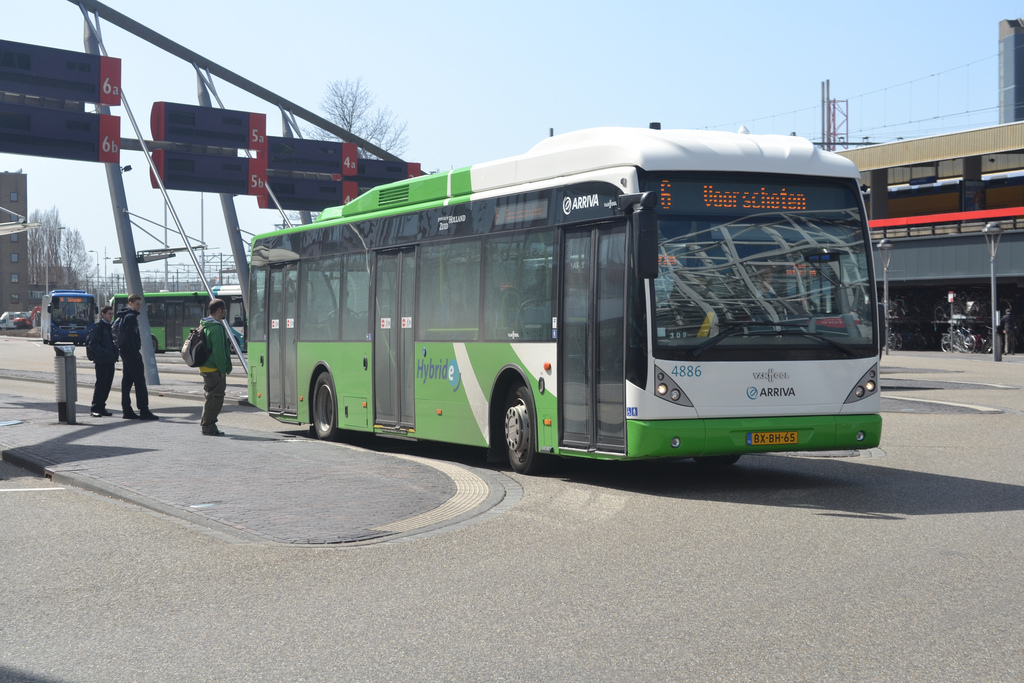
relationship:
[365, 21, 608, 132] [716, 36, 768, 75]
clouds in sky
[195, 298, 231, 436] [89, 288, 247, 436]
man standing in group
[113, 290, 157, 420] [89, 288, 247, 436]
person standing in group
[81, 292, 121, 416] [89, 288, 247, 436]
person standing in group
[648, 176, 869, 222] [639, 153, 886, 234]
display on bus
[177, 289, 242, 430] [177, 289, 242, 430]
man wears jacket